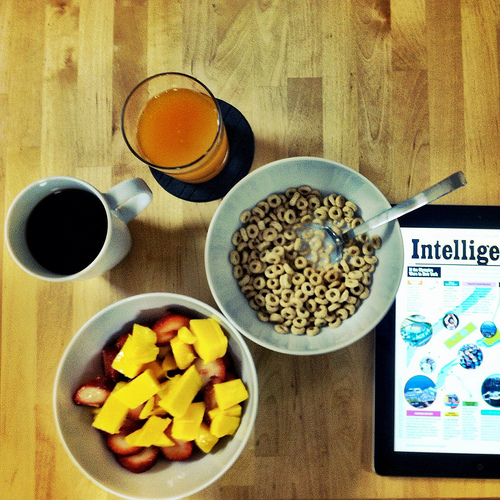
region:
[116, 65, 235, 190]
a clear glass with orange juice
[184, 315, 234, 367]
a slice of mango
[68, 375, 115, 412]
a slice of a strawberry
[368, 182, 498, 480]
an ipad with a screen displaying "intellige"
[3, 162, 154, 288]
a white ceramic coffee mug with coffee in it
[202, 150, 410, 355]
a white ceramic bowl of cherrios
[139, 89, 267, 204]
a black drink coaster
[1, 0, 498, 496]
a hard wood table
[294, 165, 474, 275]
a spoon in some cherrios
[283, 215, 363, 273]
milk with the cherrios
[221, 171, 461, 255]
a spoon laying in a bowl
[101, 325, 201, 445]
mango served with strawberries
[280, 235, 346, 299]
milk served with cheerios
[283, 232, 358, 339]
cheerios served with milk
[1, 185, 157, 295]
coffe cup sitting on top of table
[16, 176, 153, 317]
coffee sitting next to bowl of fruit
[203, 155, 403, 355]
the bowl of cereal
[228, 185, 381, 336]
the cereal in the bowl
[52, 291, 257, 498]
the bowl full of fruit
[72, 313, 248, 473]
the fruit in the bowl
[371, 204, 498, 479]
the tablet next to the bowls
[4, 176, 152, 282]
the white coffee mug next to the bowls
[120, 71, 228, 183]
the clear glass cup next to the bowls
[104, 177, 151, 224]
the handle on the mug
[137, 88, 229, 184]
the liquid in the clear glass cup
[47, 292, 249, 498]
Bowl of mixed fruits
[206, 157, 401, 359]
Bowl of cereal and milk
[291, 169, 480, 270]
Silver spoon in a cereal plate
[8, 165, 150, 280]
White cup filled with coffee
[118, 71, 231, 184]
Glass cup filled with juice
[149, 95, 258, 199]
Black coaster on the table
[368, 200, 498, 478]
Tablet on the table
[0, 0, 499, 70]
Light wooden dinning table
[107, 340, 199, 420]
Mango pieces in a bowl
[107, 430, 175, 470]
Strawberry pieces in a bowl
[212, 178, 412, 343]
a bowl of cereal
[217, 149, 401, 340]
a bowl of cereal and milk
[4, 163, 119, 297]
a white coffee cup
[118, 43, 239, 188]
a clear drinking glass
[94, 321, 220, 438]
chopped pineapple in a bowl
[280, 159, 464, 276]
a spoon in a bowl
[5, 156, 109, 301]
a cup with coffee in it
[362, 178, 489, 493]
a electronic tablet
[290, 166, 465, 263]
a silver spoon in a bowl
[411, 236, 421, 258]
print letter on box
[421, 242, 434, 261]
print letter on box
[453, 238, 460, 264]
print letter on box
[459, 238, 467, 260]
print letter on box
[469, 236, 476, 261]
print letter on box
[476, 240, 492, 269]
print letter on box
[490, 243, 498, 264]
print letter on box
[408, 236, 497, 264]
print letters on box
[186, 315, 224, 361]
piece of fruit in the white bowl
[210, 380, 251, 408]
piece of fruit in the white bowl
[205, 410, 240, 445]
piece of fruit in the white bowl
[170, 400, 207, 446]
piece of fruit in the white bowl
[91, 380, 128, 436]
piece of fruit in the white bowl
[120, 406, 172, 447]
piece of fruit in the white bowl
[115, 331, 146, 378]
piece of fruit in the white bowl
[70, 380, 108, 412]
piece of fruit in the white bowl